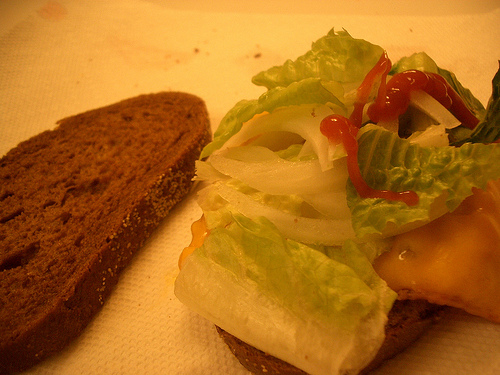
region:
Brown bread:
[3, 74, 213, 374]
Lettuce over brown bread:
[177, 17, 482, 373]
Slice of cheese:
[390, 159, 496, 324]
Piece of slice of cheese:
[174, 214, 206, 275]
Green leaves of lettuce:
[360, 128, 498, 238]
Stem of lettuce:
[161, 307, 403, 372]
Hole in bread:
[0, 230, 55, 282]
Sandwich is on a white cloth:
[6, 0, 498, 373]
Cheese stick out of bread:
[394, 190, 496, 344]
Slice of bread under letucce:
[206, 300, 460, 373]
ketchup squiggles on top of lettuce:
[312, 31, 483, 216]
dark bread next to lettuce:
[27, 55, 234, 342]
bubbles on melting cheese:
[372, 157, 492, 322]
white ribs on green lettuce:
[360, 116, 426, 166]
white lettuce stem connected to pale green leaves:
[162, 207, 374, 367]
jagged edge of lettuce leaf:
[245, 20, 370, 86]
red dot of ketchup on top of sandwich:
[310, 90, 350, 141]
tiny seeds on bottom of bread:
[85, 160, 190, 300]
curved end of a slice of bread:
[85, 72, 215, 212]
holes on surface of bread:
[7, 155, 92, 270]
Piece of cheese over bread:
[391, 199, 499, 348]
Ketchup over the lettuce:
[304, 44, 481, 211]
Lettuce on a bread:
[153, 14, 484, 364]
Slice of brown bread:
[3, 80, 213, 368]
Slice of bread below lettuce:
[198, 287, 463, 372]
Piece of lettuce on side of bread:
[166, 215, 401, 370]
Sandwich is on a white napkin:
[6, 10, 499, 373]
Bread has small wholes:
[0, 168, 118, 284]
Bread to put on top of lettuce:
[0, 76, 220, 371]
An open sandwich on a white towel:
[35, 50, 472, 345]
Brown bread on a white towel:
[35, 87, 211, 250]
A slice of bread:
[35, 93, 159, 283]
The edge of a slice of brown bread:
[78, 193, 176, 312]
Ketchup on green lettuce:
[296, 53, 436, 193]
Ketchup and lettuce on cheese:
[232, 50, 456, 282]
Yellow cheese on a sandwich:
[403, 237, 483, 334]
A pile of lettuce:
[204, 167, 385, 339]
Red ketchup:
[311, 36, 429, 196]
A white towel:
[133, 316, 200, 359]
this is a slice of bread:
[1, 81, 186, 333]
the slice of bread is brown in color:
[2, 85, 159, 347]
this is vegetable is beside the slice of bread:
[228, 58, 464, 359]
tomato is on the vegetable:
[338, 63, 467, 181]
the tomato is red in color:
[330, 68, 455, 142]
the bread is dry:
[20, 89, 166, 294]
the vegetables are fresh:
[241, 275, 355, 324]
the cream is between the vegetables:
[424, 225, 494, 291]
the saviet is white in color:
[115, 285, 162, 374]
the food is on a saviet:
[136, 261, 173, 352]